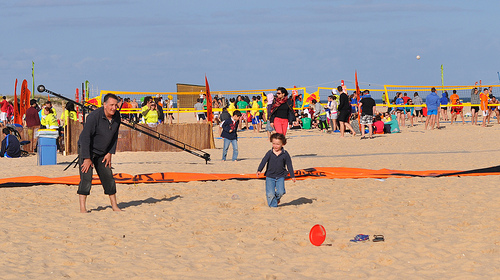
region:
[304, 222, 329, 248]
Red moving frisbee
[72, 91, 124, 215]
Man standing in sand with no shoes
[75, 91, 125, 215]
Man wearing gray standing in the sand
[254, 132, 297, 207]
Small boy wearing a gray shirt and jeans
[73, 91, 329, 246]
Man and boy playing with a frisbee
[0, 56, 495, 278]
Many people at a beach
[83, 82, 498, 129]
Four yellow volleyball nets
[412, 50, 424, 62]
Volleyball high in the sky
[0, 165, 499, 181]
Collapsed orange banner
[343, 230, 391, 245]
Sandles in the sand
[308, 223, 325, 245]
red frisbee rolling on the ground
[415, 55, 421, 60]
white volleyball in the air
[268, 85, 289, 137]
woman with red scarf and pants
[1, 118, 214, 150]
section of fence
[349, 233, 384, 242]
blue flip flops on the ground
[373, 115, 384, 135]
person in a red shirt sitting on the ground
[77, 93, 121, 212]
man in black shirt bending over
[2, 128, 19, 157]
person in blue shirt sitting on the ground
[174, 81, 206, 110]
small wooden building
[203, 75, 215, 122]
bright orange flag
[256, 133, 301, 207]
a child on beach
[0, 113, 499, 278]
a brown sandy beach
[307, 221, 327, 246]
a round red frisbee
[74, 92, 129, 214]
a man standing on beach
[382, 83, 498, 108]
a long yellow net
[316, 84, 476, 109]
a long yellow net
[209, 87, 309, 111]
a long yellow net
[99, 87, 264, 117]
a long yellow net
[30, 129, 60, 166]
a blue trash can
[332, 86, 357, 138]
a man walking on beach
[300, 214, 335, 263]
red frisbee on sand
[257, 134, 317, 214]
young child on beach during sunny day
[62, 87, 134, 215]
man resting hands on legs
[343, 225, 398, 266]
two pairs of shoes in sand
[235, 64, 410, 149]
busy beach scene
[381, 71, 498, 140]
volleyball match on beach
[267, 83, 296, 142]
woman wearing red scarf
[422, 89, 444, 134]
man wearing blue shorts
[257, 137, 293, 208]
small child wearing jeans on beach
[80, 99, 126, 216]
man with grey sweater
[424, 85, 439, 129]
a person standing on beach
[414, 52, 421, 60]
a white volleyball in air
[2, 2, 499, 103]
a hazy blue sky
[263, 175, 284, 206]
child's pair of jeans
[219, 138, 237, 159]
men's pair of jeans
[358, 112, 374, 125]
men's pair of shorts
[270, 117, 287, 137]
red pair of shorts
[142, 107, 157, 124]
a bright yellow shirt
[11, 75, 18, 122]
a large red flag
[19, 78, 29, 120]
a large red flag